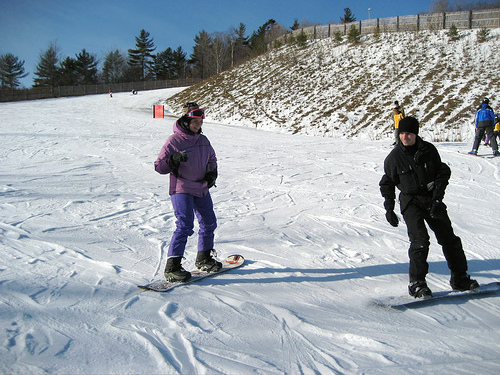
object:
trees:
[126, 28, 160, 89]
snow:
[0, 84, 500, 374]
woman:
[154, 102, 224, 284]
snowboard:
[135, 254, 246, 293]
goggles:
[184, 104, 211, 118]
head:
[184, 102, 206, 134]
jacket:
[155, 121, 218, 197]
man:
[379, 116, 480, 299]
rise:
[151, 91, 165, 119]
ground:
[0, 86, 500, 375]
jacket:
[475, 102, 497, 130]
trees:
[345, 23, 367, 51]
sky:
[0, 0, 500, 90]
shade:
[195, 259, 500, 287]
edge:
[449, 269, 480, 291]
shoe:
[450, 261, 480, 291]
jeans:
[165, 193, 221, 282]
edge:
[247, 266, 309, 273]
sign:
[152, 99, 163, 116]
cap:
[397, 116, 421, 136]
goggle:
[176, 106, 208, 120]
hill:
[255, 29, 465, 137]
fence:
[295, 8, 500, 40]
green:
[256, 33, 341, 79]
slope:
[168, 27, 500, 140]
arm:
[155, 138, 188, 175]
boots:
[407, 227, 479, 296]